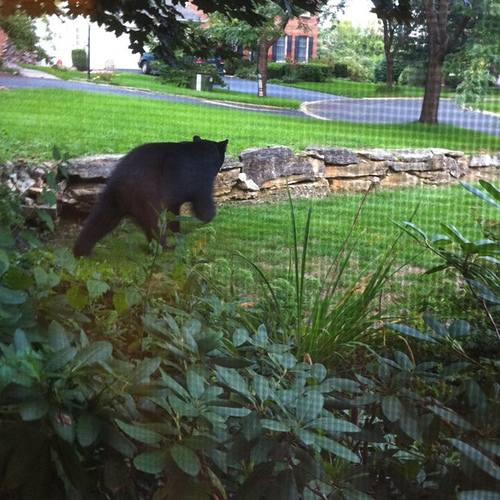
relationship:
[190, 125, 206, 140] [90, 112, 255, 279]
ear of bear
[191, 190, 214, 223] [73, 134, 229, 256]
leg of bear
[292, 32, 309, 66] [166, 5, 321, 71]
window of building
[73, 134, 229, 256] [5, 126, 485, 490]
bear in foreground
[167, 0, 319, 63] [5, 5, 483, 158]
building in background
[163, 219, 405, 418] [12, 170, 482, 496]
plants in landscaping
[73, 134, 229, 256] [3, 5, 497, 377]
bear in window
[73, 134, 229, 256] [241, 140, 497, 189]
bear by rocks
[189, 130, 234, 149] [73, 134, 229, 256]
ears of bear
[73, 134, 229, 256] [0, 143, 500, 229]
bear by rocks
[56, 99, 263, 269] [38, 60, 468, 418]
bear in wild